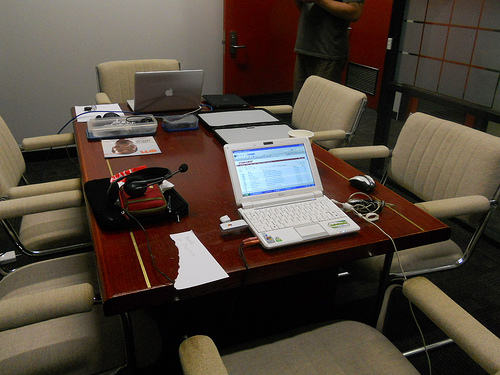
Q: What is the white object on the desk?
A: Laptop.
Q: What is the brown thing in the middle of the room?
A: Table.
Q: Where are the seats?
A: At the table.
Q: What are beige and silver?
A: Chairs.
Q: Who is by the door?
A: A person.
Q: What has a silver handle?
A: Door.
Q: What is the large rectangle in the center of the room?
A: Table.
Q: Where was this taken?
A: A conference room.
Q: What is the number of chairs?
A: Six.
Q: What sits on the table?
A: Two open laptops.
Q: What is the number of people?
A: One.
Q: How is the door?
A: It is ajar.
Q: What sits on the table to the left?
A: Headphones with microphone.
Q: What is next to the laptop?
A: A piece of ripped paper.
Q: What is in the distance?
A: A white wall.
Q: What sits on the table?
A: Binders.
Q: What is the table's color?
A: Dark wood.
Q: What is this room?
A: Conference.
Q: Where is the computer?
A: Table.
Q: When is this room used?
A: Meetings.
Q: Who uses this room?
A: Business people.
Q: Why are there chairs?
A: Seating.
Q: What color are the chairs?
A: Tan.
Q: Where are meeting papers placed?
A: Table.